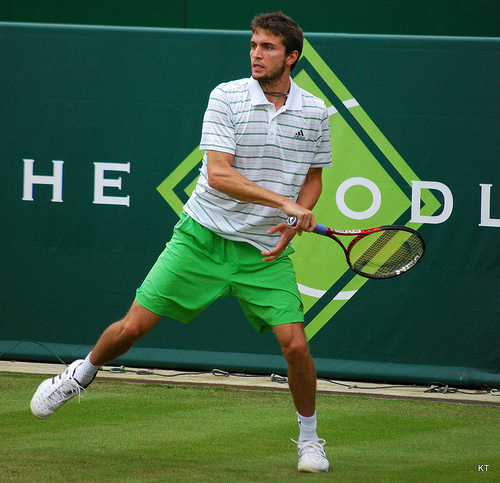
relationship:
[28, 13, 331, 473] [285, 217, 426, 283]
man holding racket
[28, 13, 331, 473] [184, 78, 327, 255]
man wearing shirt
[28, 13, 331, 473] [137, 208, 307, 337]
man wearing shorts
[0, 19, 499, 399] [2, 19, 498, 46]
wall has an edge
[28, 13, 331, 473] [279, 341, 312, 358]
man has a knee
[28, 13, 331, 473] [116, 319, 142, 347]
man has a knee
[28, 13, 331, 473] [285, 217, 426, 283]
man swinging racket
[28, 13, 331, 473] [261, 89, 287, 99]
man wearing necklace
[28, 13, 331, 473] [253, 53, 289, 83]
man has a beard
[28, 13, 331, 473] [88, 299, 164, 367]
man has a leg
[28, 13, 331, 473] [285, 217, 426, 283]
man has a racket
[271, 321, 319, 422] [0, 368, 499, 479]
leg near grass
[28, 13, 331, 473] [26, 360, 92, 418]
man wearing shoe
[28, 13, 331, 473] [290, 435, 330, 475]
man wearing shoe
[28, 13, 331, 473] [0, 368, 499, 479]
man standing on grass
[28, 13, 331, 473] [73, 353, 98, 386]
man wearing a sock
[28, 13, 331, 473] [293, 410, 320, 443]
man wearing a sock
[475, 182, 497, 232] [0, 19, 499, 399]
letter on wall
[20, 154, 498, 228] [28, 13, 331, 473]
word behind man